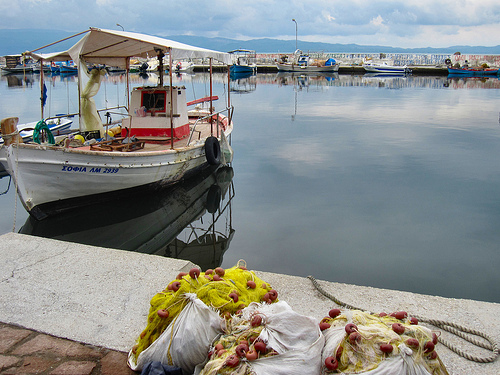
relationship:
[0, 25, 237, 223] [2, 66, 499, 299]
boat on water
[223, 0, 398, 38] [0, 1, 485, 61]
clouds in sky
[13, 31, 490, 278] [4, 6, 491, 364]
scene at harbor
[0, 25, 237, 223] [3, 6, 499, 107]
boat in background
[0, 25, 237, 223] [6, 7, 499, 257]
boat on water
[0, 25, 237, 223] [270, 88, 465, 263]
boat on water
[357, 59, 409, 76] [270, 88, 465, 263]
boat on water